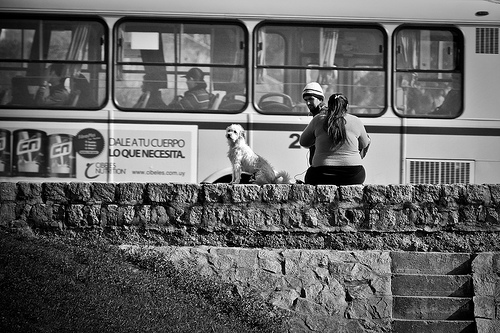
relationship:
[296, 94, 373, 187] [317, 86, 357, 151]
people has dark hair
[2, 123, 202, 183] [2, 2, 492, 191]
sign on bus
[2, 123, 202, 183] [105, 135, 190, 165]
sign in spanish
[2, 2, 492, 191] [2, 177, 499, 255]
bus next wall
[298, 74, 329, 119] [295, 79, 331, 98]
man wears knit cap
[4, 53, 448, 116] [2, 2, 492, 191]
people riding bus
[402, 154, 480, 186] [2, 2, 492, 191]
vent on bus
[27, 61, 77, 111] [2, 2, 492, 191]
man sits in bus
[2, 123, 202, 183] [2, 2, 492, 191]
advertisement on bus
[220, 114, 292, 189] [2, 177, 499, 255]
dog on wall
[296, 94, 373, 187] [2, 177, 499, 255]
people sits on wall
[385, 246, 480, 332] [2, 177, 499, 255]
steps leading to wall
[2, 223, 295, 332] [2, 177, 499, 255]
grass next wall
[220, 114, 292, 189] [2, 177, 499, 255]
dog sits on wall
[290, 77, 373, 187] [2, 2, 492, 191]
people outside bus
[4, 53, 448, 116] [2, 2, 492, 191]
people sitting in bus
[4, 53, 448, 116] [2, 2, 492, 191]
people sits on bus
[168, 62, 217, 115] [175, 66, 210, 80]
man wears cap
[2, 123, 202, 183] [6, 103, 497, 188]
advertisement on side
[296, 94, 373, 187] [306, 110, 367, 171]
people wears shirt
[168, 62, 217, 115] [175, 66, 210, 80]
man wears hat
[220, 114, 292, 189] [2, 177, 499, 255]
dog on stone wall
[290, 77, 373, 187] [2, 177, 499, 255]
people near stone wall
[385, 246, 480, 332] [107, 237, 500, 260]
stairs leads to roadway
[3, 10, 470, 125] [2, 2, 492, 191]
windows on bus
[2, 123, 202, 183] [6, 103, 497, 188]
ad on side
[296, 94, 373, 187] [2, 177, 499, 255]
people sits on stone wall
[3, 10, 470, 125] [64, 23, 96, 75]
window has curtain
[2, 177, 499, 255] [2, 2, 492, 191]
wall next to bus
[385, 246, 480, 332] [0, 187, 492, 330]
steps are on wall